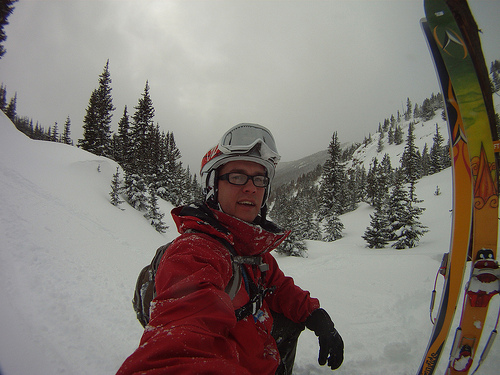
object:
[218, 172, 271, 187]
glasses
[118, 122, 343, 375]
man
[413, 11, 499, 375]
skis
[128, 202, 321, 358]
coat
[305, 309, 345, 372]
gloves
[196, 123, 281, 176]
helmet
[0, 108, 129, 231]
hillside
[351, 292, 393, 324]
tracks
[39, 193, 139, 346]
snow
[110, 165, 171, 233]
tree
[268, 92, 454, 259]
trees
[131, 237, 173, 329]
backpack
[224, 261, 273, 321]
straps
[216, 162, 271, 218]
face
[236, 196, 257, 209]
mouth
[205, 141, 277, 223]
head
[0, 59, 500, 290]
valley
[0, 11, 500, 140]
sky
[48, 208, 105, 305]
ground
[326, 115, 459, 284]
mountainside